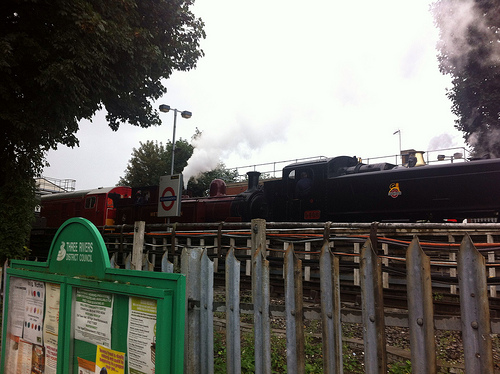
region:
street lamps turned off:
[132, 80, 206, 190]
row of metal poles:
[172, 233, 489, 358]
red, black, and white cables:
[365, 228, 456, 270]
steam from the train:
[422, 10, 494, 214]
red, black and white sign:
[112, 164, 190, 222]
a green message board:
[12, 202, 184, 337]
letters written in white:
[37, 225, 106, 272]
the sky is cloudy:
[200, 36, 426, 144]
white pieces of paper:
[0, 271, 67, 370]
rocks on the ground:
[262, 302, 459, 364]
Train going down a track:
[23, 141, 498, 230]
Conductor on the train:
[288, 160, 320, 211]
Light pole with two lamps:
[151, 86, 203, 273]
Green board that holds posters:
[2, 196, 191, 369]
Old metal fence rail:
[105, 217, 482, 373]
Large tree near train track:
[5, 7, 225, 277]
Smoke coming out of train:
[154, 109, 305, 190]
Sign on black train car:
[380, 172, 407, 211]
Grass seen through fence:
[197, 323, 417, 373]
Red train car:
[24, 174, 152, 252]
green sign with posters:
[5, 221, 185, 369]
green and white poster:
[64, 293, 116, 353]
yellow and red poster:
[89, 344, 122, 369]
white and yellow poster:
[127, 300, 157, 372]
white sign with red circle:
[150, 171, 187, 216]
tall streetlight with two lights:
[160, 95, 195, 215]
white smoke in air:
[199, 117, 284, 163]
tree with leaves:
[2, 19, 150, 104]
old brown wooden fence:
[212, 240, 427, 364]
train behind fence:
[177, 150, 498, 256]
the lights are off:
[152, 86, 202, 126]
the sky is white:
[260, 12, 347, 92]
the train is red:
[44, 151, 476, 221]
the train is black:
[256, 148, 482, 219]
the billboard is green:
[2, 205, 202, 369]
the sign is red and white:
[145, 164, 195, 229]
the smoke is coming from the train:
[199, 125, 263, 165]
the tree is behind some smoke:
[454, 23, 499, 132]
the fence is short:
[250, 214, 462, 367]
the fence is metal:
[259, 207, 475, 356]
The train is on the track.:
[93, 170, 455, 237]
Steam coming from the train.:
[173, 124, 299, 156]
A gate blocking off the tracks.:
[170, 211, 476, 349]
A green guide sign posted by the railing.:
[13, 208, 180, 370]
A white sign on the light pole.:
[136, 161, 196, 223]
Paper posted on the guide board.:
[16, 286, 67, 367]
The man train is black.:
[279, 151, 458, 228]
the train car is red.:
[38, 173, 128, 220]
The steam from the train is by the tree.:
[416, 21, 490, 86]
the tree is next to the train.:
[3, 13, 125, 226]